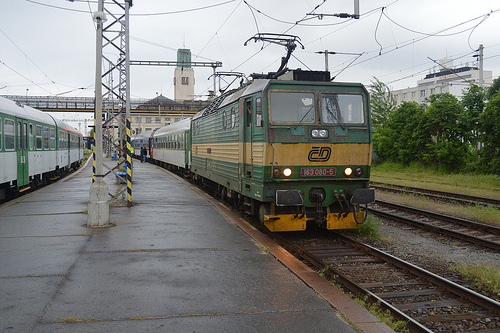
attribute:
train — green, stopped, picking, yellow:
[133, 69, 373, 234]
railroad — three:
[256, 178, 499, 325]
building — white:
[369, 47, 497, 110]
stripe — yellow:
[189, 141, 373, 166]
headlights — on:
[275, 167, 362, 178]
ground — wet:
[0, 151, 394, 331]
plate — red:
[303, 167, 338, 178]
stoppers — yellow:
[262, 208, 367, 234]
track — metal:
[280, 182, 498, 331]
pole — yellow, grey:
[126, 117, 134, 206]